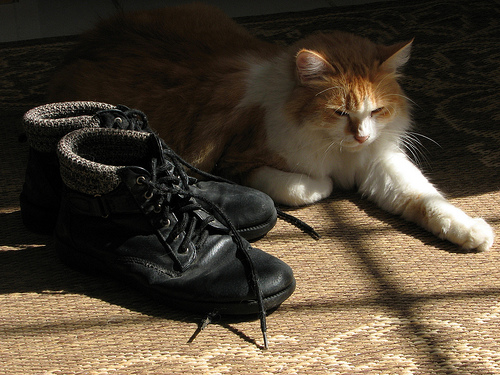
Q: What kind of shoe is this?
A: A black boot.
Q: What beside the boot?
A: A cat.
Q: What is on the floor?
A: A tan rug.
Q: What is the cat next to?
A: Black shoes.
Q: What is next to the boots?
A: A cat.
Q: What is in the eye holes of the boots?
A: Black laces.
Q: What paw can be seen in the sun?
A: The left paw.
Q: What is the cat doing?
A: Laying down.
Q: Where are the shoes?
A: On the ground.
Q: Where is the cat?
A: On the ground.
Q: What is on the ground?
A: Cat and boots.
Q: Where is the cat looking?
A: Down.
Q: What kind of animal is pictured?
A: Cat.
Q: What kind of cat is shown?
A: Tabby.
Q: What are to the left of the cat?
A: Shoes.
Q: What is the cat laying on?
A: Carpet.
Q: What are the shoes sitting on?
A: Carpet.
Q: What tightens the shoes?
A: Laces.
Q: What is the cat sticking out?
A: Paw.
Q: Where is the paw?
A: Reaching into the sunlight.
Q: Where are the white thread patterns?
A: On the rug.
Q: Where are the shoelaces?
A: On the boots.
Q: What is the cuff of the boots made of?
A: Gray fabric.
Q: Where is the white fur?
A: On the cat.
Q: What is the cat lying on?
A: A brown rug.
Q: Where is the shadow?
A: On the carpet.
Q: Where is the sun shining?
A: On the cat.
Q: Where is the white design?
A: On the carpet.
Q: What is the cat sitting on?
A: A rug.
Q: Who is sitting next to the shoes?
A: A cat.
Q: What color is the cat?
A: Orange and white.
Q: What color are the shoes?
A: Black.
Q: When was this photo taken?
A: Daytime.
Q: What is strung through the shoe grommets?
A: Laces.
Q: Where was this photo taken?
A: In a house.